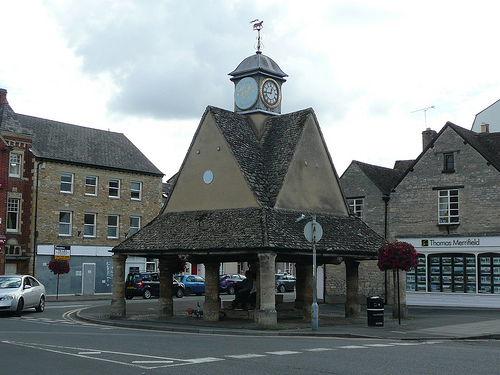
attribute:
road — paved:
[99, 311, 304, 372]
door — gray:
[60, 257, 121, 305]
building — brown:
[50, 147, 271, 309]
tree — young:
[374, 239, 418, 326]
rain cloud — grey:
[54, 4, 258, 121]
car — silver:
[0, 272, 45, 315]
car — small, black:
[125, 269, 187, 301]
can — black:
[361, 292, 391, 329]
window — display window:
[403, 252, 499, 292]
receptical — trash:
[365, 290, 389, 327]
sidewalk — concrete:
[377, 292, 490, 325]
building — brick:
[14, 111, 164, 302]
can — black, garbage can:
[364, 287, 389, 328]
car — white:
[0, 274, 49, 316]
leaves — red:
[378, 240, 417, 270]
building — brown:
[331, 117, 484, 302]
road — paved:
[334, 330, 484, 369]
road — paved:
[9, 300, 88, 368]